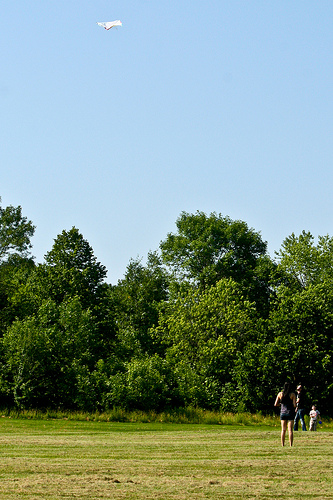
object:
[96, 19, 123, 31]
kite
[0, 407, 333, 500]
grass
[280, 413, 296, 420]
shorts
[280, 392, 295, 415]
shirt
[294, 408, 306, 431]
jeans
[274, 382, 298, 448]
person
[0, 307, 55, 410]
tree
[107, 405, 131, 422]
weeds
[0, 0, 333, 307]
sky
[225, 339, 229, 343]
leaves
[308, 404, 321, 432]
people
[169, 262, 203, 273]
branches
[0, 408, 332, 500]
field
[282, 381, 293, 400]
hair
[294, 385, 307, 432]
man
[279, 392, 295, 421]
clothes